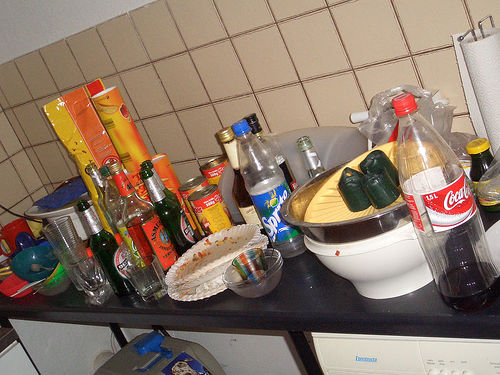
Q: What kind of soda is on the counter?
A: Coca Cola.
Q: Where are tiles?
A: On the wall.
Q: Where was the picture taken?
A: In a kitchen.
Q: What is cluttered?
A: Countertop.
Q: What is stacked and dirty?
A: Paper plates.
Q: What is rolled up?
A: Paper towels.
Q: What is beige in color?
A: Tiles on the wall.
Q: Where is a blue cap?
A: On Sprite bottle.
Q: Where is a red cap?
A: On Coca-Cola bottle.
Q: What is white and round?
A: Plates.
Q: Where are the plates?
A: On counter.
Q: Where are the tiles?
A: Above counter.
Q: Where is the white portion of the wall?
A: Over dark tiles.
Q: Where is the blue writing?
A: On the dishwasher.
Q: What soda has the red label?
A: Coca-Cola.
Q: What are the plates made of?
A: Paper.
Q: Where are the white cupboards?
A: Under black counter top.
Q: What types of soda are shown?
A: Coca-Cola and Sprite.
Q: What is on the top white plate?
A: Food bits.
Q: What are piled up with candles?
A: Bowls.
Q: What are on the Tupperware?
A: Candles.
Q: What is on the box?
A: Chips.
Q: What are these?
A: Bottles.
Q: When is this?
A: Daytime.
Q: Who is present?
A: No one.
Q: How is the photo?
A: Clear.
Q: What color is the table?
A: Black.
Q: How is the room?
A: Messy.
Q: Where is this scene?
A: In a kitchen.